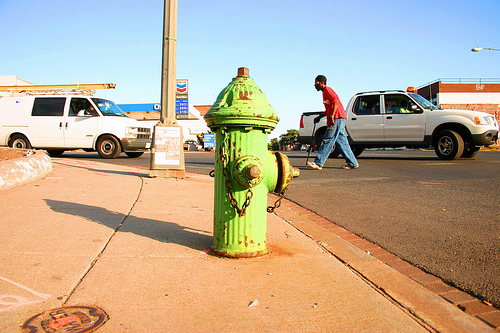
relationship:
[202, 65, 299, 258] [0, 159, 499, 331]
hydrant on sidewalk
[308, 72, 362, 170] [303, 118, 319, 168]
person has cane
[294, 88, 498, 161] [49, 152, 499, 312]
vehicle on street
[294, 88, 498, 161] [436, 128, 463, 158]
vehicle has wheel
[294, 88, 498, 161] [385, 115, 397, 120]
vehicle has handles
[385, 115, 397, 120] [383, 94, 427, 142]
handles on door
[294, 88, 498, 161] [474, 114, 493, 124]
vehicle has headlight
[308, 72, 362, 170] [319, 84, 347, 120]
person wearing shirt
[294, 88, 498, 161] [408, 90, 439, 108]
vehicle has windshield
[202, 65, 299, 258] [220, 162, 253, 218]
hydrant has chain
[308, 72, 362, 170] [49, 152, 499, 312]
person crossing street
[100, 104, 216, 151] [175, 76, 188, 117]
station has sign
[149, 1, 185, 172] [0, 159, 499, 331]
pole on sidewalk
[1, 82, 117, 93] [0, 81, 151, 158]
ladder on van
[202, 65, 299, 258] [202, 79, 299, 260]
hydrant has rust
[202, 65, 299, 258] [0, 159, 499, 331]
hydrant near edge of sidewalk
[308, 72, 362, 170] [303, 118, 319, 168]
person using cane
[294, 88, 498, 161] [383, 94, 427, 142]
vehicle has door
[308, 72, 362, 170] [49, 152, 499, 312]
person walking across street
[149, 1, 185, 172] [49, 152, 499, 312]
pole on street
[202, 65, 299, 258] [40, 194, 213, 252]
hydrant has shadow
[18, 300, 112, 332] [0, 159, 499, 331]
cover on sidewalk